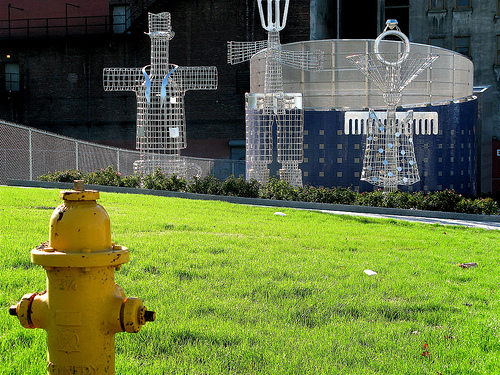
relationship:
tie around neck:
[142, 64, 180, 109] [142, 59, 180, 72]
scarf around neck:
[142, 64, 180, 109] [142, 59, 180, 72]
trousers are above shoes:
[245, 94, 302, 167] [245, 166, 302, 192]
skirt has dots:
[356, 103, 423, 187] [366, 114, 418, 188]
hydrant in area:
[12, 191, 155, 372] [2, 182, 500, 368]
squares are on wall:
[302, 121, 482, 194] [227, 6, 498, 196]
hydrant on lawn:
[12, 191, 155, 372] [2, 182, 500, 368]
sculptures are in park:
[106, 11, 416, 198] [5, 5, 500, 373]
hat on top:
[144, 12, 176, 41] [146, 11, 176, 42]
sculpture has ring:
[346, 17, 440, 208] [376, 20, 410, 68]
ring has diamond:
[376, 20, 410, 68] [383, 17, 401, 30]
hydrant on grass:
[12, 191, 155, 372] [2, 182, 500, 368]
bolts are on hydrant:
[11, 306, 155, 323] [12, 191, 155, 372]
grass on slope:
[2, 182, 500, 368] [4, 188, 500, 370]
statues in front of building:
[106, 11, 416, 198] [233, 4, 496, 192]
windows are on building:
[310, 5, 416, 103] [233, 4, 496, 192]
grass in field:
[2, 182, 500, 368] [2, 182, 500, 368]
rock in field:
[453, 262, 479, 271] [2, 182, 500, 368]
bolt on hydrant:
[145, 310, 157, 321] [12, 191, 155, 372]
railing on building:
[2, 12, 189, 51] [5, 5, 251, 180]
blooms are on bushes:
[28, 169, 488, 220] [50, 170, 498, 224]